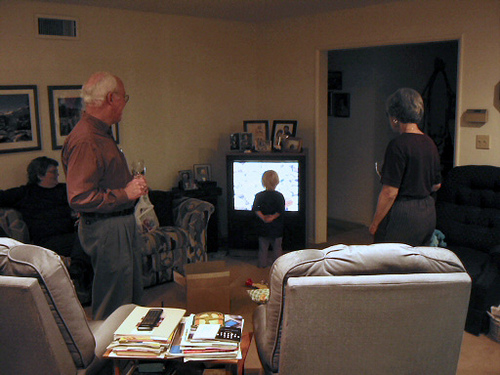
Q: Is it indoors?
A: Yes, it is indoors.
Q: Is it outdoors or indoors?
A: It is indoors.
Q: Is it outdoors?
A: No, it is indoors.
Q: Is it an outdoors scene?
A: No, it is indoors.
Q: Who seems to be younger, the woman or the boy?
A: The boy is younger than the woman.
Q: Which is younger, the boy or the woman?
A: The boy is younger than the woman.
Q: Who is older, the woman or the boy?
A: The woman is older than the boy.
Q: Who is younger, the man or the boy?
A: The boy is younger than the man.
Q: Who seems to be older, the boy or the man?
A: The man is older than the boy.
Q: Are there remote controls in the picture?
A: Yes, there is a remote control.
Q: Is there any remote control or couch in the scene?
A: Yes, there is a remote control.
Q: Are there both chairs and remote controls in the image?
A: Yes, there are both a remote control and a chair.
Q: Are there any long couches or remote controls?
A: Yes, there is a long remote control.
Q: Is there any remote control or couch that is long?
A: Yes, the remote control is long.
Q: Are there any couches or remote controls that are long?
A: Yes, the remote control is long.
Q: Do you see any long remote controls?
A: Yes, there is a long remote control.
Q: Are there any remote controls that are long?
A: Yes, there is a remote control that is long.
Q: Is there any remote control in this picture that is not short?
A: Yes, there is a long remote control.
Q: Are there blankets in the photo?
A: No, there are no blankets.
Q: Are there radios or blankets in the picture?
A: No, there are no blankets or radios.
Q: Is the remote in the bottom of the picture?
A: Yes, the remote is in the bottom of the image.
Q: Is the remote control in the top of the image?
A: No, the remote control is in the bottom of the image.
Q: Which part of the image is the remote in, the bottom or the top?
A: The remote is in the bottom of the image.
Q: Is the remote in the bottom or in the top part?
A: The remote is in the bottom of the image.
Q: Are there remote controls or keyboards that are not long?
A: No, there is a remote control but it is long.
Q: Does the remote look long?
A: Yes, the remote is long.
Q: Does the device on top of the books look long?
A: Yes, the remote is long.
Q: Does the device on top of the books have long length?
A: Yes, the remote is long.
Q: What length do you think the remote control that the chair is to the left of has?
A: The remote has long length.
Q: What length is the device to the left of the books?
A: The remote is long.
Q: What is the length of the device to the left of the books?
A: The remote is long.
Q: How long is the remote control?
A: The remote control is long.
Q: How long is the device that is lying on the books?
A: The remote control is long.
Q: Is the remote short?
A: No, the remote is long.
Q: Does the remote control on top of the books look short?
A: No, the remote control is long.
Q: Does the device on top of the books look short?
A: No, the remote control is long.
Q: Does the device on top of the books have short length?
A: No, the remote control is long.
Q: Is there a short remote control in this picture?
A: No, there is a remote control but it is long.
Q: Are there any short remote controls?
A: No, there is a remote control but it is long.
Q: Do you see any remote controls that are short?
A: No, there is a remote control but it is long.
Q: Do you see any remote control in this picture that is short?
A: No, there is a remote control but it is long.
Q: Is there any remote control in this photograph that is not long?
A: No, there is a remote control but it is long.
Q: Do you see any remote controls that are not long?
A: No, there is a remote control but it is long.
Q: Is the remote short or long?
A: The remote is long.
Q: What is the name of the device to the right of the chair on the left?
A: The device is a remote control.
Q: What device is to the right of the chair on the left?
A: The device is a remote control.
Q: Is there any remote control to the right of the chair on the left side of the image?
A: Yes, there is a remote control to the right of the chair.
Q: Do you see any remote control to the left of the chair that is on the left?
A: No, the remote control is to the right of the chair.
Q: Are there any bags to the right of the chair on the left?
A: No, there is a remote control to the right of the chair.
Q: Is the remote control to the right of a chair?
A: Yes, the remote control is to the right of a chair.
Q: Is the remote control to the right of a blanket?
A: No, the remote control is to the right of a chair.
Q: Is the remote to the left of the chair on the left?
A: No, the remote is to the right of the chair.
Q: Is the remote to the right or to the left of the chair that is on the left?
A: The remote is to the right of the chair.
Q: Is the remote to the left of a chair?
A: Yes, the remote is to the left of a chair.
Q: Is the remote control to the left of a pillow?
A: No, the remote control is to the left of a chair.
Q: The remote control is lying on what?
A: The remote control is lying on the books.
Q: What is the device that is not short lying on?
A: The remote control is lying on the books.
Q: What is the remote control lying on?
A: The remote control is lying on the books.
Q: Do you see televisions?
A: Yes, there is a television.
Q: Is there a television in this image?
A: Yes, there is a television.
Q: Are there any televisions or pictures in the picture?
A: Yes, there is a television.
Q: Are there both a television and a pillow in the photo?
A: No, there is a television but no pillows.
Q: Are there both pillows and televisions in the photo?
A: No, there is a television but no pillows.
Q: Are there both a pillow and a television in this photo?
A: No, there is a television but no pillows.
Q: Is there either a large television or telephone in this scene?
A: Yes, there is a large television.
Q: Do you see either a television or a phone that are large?
A: Yes, the television is large.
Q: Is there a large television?
A: Yes, there is a large television.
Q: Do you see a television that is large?
A: Yes, there is a television that is large.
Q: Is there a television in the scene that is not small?
A: Yes, there is a large television.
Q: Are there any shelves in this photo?
A: No, there are no shelves.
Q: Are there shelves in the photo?
A: No, there are no shelves.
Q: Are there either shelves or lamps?
A: No, there are no shelves or lamps.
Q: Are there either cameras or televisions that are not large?
A: No, there is a television but it is large.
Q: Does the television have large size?
A: Yes, the television is large.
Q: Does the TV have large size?
A: Yes, the TV is large.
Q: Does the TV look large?
A: Yes, the TV is large.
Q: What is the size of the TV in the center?
A: The TV is large.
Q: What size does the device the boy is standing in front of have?
A: The TV has large size.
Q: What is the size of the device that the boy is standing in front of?
A: The TV is large.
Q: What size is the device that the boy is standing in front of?
A: The TV is large.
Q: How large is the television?
A: The television is large.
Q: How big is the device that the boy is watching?
A: The television is large.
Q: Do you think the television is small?
A: No, the television is large.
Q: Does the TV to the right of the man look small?
A: No, the television is large.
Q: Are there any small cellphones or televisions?
A: No, there is a television but it is large.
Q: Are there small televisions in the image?
A: No, there is a television but it is large.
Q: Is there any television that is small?
A: No, there is a television but it is large.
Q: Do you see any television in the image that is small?
A: No, there is a television but it is large.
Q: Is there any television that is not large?
A: No, there is a television but it is large.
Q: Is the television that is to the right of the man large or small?
A: The TV is large.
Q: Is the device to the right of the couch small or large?
A: The TV is large.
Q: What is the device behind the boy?
A: The device is a television.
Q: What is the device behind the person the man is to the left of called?
A: The device is a television.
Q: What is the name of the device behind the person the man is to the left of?
A: The device is a television.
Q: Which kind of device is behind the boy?
A: The device is a television.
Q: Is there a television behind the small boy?
A: Yes, there is a television behind the boy.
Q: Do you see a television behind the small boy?
A: Yes, there is a television behind the boy.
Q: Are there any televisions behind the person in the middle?
A: Yes, there is a television behind the boy.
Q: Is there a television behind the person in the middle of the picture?
A: Yes, there is a television behind the boy.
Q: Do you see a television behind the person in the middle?
A: Yes, there is a television behind the boy.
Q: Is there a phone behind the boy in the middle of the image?
A: No, there is a television behind the boy.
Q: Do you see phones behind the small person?
A: No, there is a television behind the boy.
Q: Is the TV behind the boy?
A: Yes, the TV is behind the boy.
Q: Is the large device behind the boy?
A: Yes, the TV is behind the boy.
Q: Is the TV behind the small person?
A: Yes, the TV is behind the boy.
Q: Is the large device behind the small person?
A: Yes, the TV is behind the boy.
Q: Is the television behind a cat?
A: No, the television is behind the boy.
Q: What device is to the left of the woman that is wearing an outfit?
A: The device is a television.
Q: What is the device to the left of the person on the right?
A: The device is a television.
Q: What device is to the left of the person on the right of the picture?
A: The device is a television.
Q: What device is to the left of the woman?
A: The device is a television.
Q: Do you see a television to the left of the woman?
A: Yes, there is a television to the left of the woman.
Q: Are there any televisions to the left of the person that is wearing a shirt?
A: Yes, there is a television to the left of the woman.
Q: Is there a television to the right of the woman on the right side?
A: No, the television is to the left of the woman.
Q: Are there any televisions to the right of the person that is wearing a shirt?
A: No, the television is to the left of the woman.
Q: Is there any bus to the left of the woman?
A: No, there is a television to the left of the woman.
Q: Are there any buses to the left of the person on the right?
A: No, there is a television to the left of the woman.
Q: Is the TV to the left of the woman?
A: Yes, the TV is to the left of the woman.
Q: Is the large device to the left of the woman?
A: Yes, the TV is to the left of the woman.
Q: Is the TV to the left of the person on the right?
A: Yes, the TV is to the left of the woman.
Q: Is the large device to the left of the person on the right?
A: Yes, the TV is to the left of the woman.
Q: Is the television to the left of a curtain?
A: No, the television is to the left of the woman.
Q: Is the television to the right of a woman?
A: No, the television is to the left of a woman.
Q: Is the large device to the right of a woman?
A: No, the television is to the left of a woman.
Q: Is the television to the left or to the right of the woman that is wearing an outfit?
A: The television is to the left of the woman.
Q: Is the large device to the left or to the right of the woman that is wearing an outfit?
A: The television is to the left of the woman.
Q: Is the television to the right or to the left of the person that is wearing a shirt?
A: The television is to the left of the woman.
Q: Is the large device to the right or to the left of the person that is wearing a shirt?
A: The television is to the left of the woman.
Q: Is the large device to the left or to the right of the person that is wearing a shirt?
A: The television is to the left of the woman.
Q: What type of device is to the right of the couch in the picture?
A: The device is a television.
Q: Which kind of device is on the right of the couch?
A: The device is a television.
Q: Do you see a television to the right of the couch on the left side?
A: Yes, there is a television to the right of the couch.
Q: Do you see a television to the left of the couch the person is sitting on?
A: No, the television is to the right of the couch.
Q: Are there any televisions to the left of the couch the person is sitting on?
A: No, the television is to the right of the couch.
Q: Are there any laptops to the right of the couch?
A: No, there is a television to the right of the couch.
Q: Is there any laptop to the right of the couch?
A: No, there is a television to the right of the couch.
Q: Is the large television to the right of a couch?
A: Yes, the TV is to the right of a couch.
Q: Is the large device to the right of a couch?
A: Yes, the TV is to the right of a couch.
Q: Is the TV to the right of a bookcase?
A: No, the TV is to the right of a couch.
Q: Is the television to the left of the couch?
A: No, the television is to the right of the couch.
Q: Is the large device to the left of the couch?
A: No, the television is to the right of the couch.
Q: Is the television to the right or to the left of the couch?
A: The television is to the right of the couch.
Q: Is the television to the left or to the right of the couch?
A: The television is to the right of the couch.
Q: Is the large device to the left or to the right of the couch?
A: The television is to the right of the couch.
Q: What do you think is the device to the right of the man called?
A: The device is a television.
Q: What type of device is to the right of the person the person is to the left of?
A: The device is a television.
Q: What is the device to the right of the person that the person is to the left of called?
A: The device is a television.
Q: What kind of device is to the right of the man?
A: The device is a television.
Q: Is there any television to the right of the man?
A: Yes, there is a television to the right of the man.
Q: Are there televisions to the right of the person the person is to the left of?
A: Yes, there is a television to the right of the man.